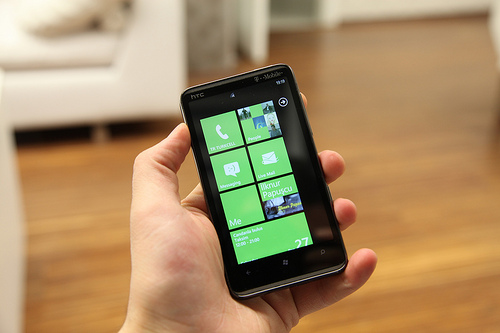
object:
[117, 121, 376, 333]
hand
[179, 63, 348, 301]
phone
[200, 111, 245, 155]
square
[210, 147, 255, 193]
square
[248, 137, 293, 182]
square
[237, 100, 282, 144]
square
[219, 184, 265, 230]
square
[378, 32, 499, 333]
floor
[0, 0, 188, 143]
couch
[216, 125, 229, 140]
phone icon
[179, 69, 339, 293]
screen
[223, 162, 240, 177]
icon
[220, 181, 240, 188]
texting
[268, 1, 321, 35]
door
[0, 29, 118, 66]
pillow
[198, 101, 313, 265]
menu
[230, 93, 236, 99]
service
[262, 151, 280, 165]
envelope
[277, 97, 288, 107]
arrow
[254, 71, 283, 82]
t-mobile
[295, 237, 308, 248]
number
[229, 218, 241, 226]
me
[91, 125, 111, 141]
leg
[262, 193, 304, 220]
scene